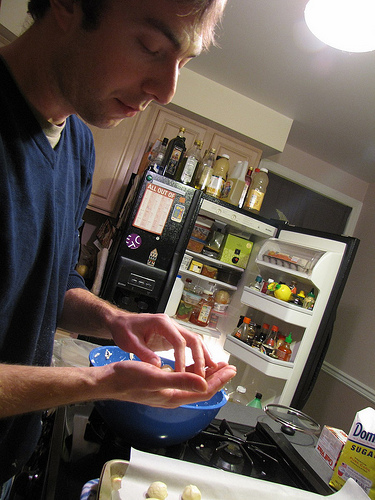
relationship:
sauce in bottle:
[275, 343, 289, 360] [278, 332, 297, 362]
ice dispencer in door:
[110, 258, 170, 311] [88, 163, 209, 340]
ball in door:
[148, 480, 172, 496] [208, 208, 366, 428]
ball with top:
[271, 282, 292, 300] [272, 281, 283, 290]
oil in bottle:
[222, 177, 245, 202] [217, 143, 250, 207]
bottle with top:
[217, 143, 250, 207] [236, 156, 247, 167]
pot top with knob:
[260, 399, 326, 440] [277, 426, 296, 435]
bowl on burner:
[86, 340, 226, 445] [86, 403, 211, 460]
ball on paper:
[148, 480, 172, 496] [118, 436, 374, 499]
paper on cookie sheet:
[118, 436, 374, 499] [97, 458, 138, 500]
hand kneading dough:
[109, 346, 241, 404] [157, 365, 182, 392]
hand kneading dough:
[110, 308, 226, 372] [157, 365, 182, 392]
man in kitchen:
[2, 0, 246, 495] [4, 2, 374, 494]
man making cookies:
[2, 0, 246, 495] [146, 474, 210, 499]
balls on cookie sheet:
[146, 474, 210, 499] [97, 458, 138, 500]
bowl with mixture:
[86, 340, 226, 445] [120, 364, 204, 403]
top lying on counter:
[272, 281, 283, 290] [253, 394, 374, 479]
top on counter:
[272, 281, 283, 290] [253, 394, 374, 479]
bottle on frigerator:
[243, 159, 275, 212] [75, 169, 361, 424]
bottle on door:
[278, 332, 297, 362] [208, 208, 366, 428]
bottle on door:
[236, 314, 255, 337] [208, 208, 366, 428]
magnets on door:
[124, 178, 188, 273] [88, 163, 209, 340]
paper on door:
[132, 177, 178, 241] [88, 163, 209, 340]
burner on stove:
[86, 403, 211, 460] [49, 395, 328, 498]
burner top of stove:
[86, 403, 211, 460] [49, 395, 328, 498]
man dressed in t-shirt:
[2, 0, 246, 495] [4, 49, 98, 483]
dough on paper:
[157, 365, 182, 392] [118, 436, 374, 499]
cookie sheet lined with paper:
[97, 443, 364, 498] [118, 436, 374, 499]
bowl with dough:
[86, 340, 226, 445] [157, 365, 182, 392]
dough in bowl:
[157, 365, 182, 392] [86, 340, 226, 445]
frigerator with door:
[75, 169, 361, 424] [208, 208, 366, 428]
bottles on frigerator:
[142, 116, 271, 216] [75, 169, 361, 424]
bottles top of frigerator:
[142, 116, 271, 216] [75, 169, 361, 424]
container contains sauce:
[273, 281, 290, 301] [275, 343, 290, 362]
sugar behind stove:
[326, 403, 374, 492] [49, 395, 328, 498]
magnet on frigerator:
[123, 231, 145, 252] [75, 169, 361, 424]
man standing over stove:
[2, 0, 246, 495] [49, 395, 328, 498]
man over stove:
[2, 0, 246, 495] [49, 395, 328, 498]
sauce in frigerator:
[275, 343, 289, 360] [75, 169, 361, 424]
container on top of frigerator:
[273, 281, 290, 301] [75, 169, 361, 424]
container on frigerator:
[273, 281, 290, 301] [75, 169, 361, 424]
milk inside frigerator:
[162, 275, 188, 326] [73, 153, 365, 424]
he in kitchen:
[2, 0, 246, 495] [4, 2, 374, 494]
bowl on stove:
[86, 340, 226, 445] [49, 395, 328, 498]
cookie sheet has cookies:
[97, 458, 138, 500] [146, 474, 210, 499]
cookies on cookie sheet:
[146, 474, 210, 499] [97, 458, 138, 500]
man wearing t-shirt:
[2, 0, 246, 495] [0, 49, 98, 482]